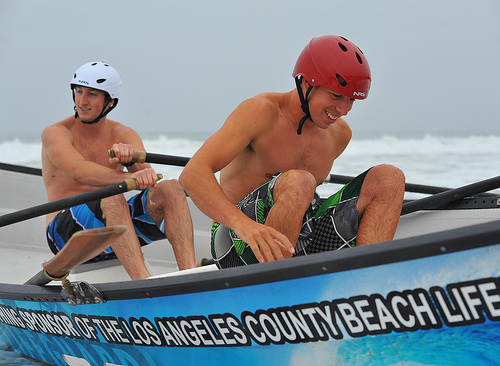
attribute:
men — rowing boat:
[39, 35, 406, 281]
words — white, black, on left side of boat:
[0, 279, 499, 348]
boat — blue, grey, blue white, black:
[1, 161, 499, 365]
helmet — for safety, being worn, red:
[291, 37, 372, 103]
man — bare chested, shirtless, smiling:
[176, 34, 408, 267]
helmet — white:
[69, 62, 122, 102]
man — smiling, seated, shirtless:
[41, 62, 198, 281]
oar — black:
[109, 148, 454, 196]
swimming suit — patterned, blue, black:
[47, 187, 170, 264]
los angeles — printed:
[119, 311, 251, 348]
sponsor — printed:
[16, 305, 80, 338]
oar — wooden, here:
[400, 177, 499, 216]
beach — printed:
[334, 287, 441, 337]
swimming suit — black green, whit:
[210, 165, 370, 269]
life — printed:
[429, 279, 499, 326]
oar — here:
[0, 172, 162, 228]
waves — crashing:
[1, 132, 499, 195]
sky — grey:
[1, 0, 499, 129]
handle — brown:
[124, 172, 163, 191]